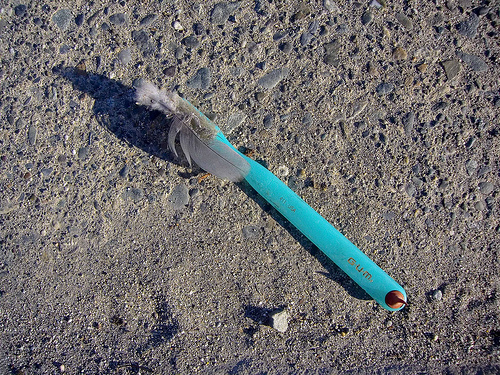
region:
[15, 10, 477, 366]
gray and rough surface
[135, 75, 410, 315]
turquoise toothbrush lying on ground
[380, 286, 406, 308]
pointy rubber tip on end of toothbrush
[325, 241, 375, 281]
name of company in gold lettering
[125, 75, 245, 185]
fluffy and smooth ends of feather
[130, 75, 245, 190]
feather covering toothbrush bristles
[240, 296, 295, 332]
gray pebble reflecting light over its shadow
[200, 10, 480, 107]
rocks embedded in concrete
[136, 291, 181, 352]
black triangular oily spot on surface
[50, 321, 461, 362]
grains of sand over surface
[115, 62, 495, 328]
blue toothbrush laying in the dirt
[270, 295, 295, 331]
pebble in the dirt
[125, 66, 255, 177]
gray bird feather on a brush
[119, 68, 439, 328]
blue toothbrush laying in the dirt with GUM logo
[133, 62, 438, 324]
blue toothbrush laying in the dirt with dirt on it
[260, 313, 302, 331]
pebble laying on the ground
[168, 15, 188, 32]
little white pebble in the dirt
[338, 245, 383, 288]
GUM logo on the toothbrush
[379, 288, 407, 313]
rubber gum cleaner on toothbrush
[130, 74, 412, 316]
A dirty toothbrush in the street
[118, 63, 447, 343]
Toothbrush in the sand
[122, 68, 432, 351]
Green Toothbrush in the sand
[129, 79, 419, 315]
Toothbrush on the ground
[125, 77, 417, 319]
Toothbrush is on the ground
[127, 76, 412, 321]
Blue toothbrush on the ground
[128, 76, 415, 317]
Blue toothbrush is on the ground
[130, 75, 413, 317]
Toothbrush on the sand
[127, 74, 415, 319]
Toothbrush is on the sand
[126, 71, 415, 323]
Blue toothbrush on the sand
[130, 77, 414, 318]
Blue toothbrush is on the sand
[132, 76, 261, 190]
Feather stuck to toothbrush head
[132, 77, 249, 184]
Feather is stuck to blue toothbrush